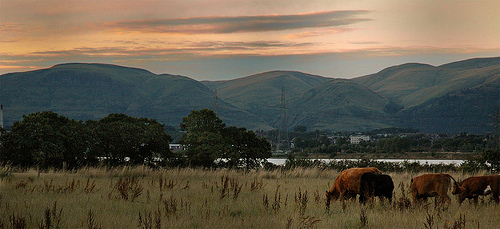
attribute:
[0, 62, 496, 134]
mountains — green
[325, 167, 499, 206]
animals — grazing, fat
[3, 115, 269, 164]
trees — full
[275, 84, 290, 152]
tower — metal, modern, cellular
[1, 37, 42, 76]
sun — setting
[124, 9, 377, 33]
clouds — gray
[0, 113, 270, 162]
leaves — green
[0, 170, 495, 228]
field — tall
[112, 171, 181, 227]
weeds — brown, tall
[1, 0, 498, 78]
sky — gorgeous, red, orange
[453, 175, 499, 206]
cow — brown, white